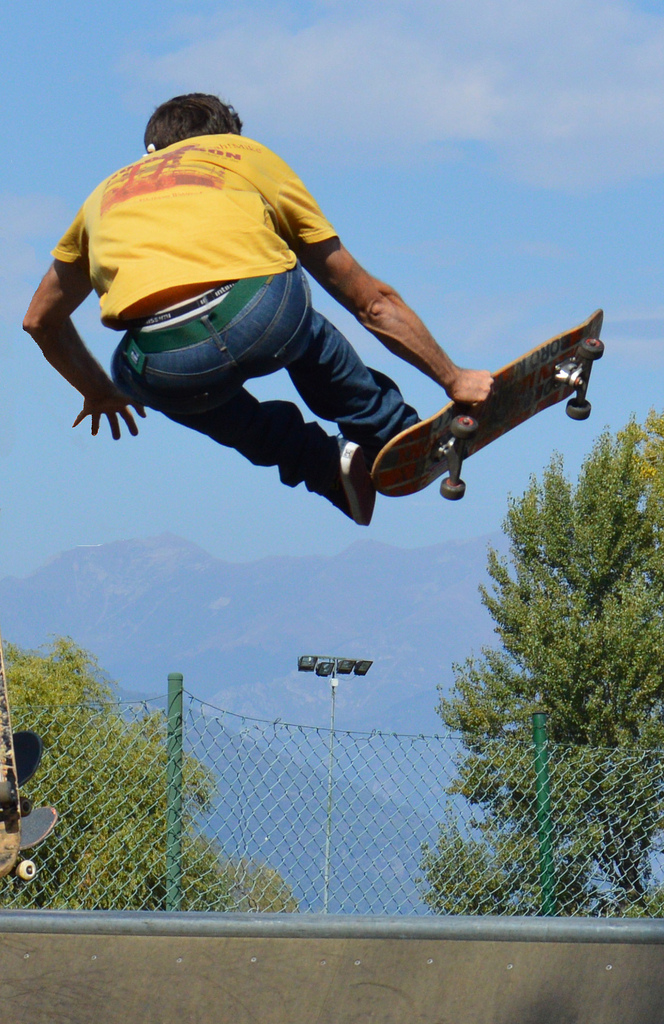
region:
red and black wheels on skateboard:
[542, 307, 612, 425]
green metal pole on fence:
[527, 707, 572, 916]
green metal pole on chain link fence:
[138, 669, 244, 907]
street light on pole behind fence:
[286, 642, 379, 912]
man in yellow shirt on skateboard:
[21, 84, 609, 526]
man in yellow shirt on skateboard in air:
[24, 76, 630, 526]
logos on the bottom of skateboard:
[371, 307, 612, 514]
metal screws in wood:
[411, 945, 626, 981]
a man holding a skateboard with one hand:
[22, 91, 605, 526]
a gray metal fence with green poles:
[3, 677, 661, 940]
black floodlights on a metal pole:
[295, 653, 372, 914]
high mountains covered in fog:
[1, 536, 661, 914]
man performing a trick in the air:
[22, 90, 607, 527]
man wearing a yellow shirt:
[20, 92, 492, 525]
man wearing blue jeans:
[21, 93, 493, 525]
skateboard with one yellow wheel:
[16, 804, 59, 882]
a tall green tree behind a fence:
[0, 412, 663, 939]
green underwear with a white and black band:
[128, 277, 268, 353]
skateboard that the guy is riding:
[353, 304, 626, 522]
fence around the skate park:
[10, 671, 654, 952]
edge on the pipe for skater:
[2, 907, 658, 966]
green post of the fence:
[151, 672, 205, 914]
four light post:
[286, 626, 378, 918]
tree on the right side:
[426, 412, 660, 915]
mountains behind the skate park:
[3, 516, 658, 903]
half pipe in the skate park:
[2, 896, 662, 1022]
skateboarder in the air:
[23, 79, 482, 529]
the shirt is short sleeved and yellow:
[48, 130, 339, 334]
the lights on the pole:
[297, 652, 373, 911]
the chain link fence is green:
[0, 675, 662, 914]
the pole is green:
[166, 672, 184, 911]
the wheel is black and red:
[450, 413, 478, 437]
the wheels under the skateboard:
[371, 307, 602, 499]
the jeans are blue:
[110, 259, 423, 499]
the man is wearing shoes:
[21, 92, 492, 524]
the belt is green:
[125, 275, 268, 373]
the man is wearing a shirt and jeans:
[20, 92, 495, 524]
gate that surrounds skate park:
[6, 642, 653, 940]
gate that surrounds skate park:
[1, 663, 654, 930]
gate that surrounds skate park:
[4, 642, 661, 937]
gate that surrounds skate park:
[5, 631, 661, 957]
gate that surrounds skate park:
[1, 637, 661, 943]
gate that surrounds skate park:
[5, 634, 662, 951]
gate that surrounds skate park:
[2, 633, 660, 936]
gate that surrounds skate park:
[4, 625, 658, 951]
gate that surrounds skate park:
[12, 645, 650, 945]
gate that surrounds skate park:
[0, 660, 661, 955]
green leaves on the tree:
[494, 562, 563, 597]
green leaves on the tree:
[641, 692, 661, 744]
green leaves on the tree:
[551, 682, 594, 773]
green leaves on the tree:
[114, 842, 142, 888]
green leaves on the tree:
[500, 600, 537, 653]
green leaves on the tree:
[586, 716, 604, 767]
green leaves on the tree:
[572, 845, 611, 881]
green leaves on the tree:
[489, 805, 547, 873]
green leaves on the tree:
[457, 801, 485, 876]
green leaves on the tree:
[582, 669, 652, 769]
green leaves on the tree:
[552, 591, 620, 685]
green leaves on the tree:
[111, 811, 126, 854]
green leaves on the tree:
[172, 862, 264, 915]